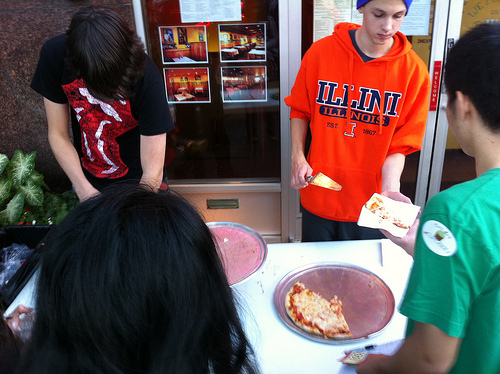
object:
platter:
[271, 261, 397, 344]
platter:
[202, 218, 270, 290]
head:
[39, 183, 253, 372]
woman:
[17, 175, 260, 374]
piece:
[349, 185, 432, 237]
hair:
[59, 4, 159, 112]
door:
[288, 0, 450, 245]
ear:
[451, 89, 472, 122]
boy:
[352, 19, 499, 373]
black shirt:
[30, 32, 176, 189]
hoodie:
[282, 21, 431, 223]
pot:
[270, 261, 396, 348]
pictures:
[149, 19, 270, 111]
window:
[138, 2, 285, 175]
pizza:
[362, 190, 413, 232]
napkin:
[356, 192, 421, 239]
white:
[272, 340, 299, 371]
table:
[279, 238, 387, 265]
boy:
[285, 1, 429, 241]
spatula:
[300, 171, 342, 191]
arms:
[137, 98, 167, 191]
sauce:
[284, 276, 352, 340]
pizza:
[285, 279, 351, 336]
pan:
[274, 260, 396, 344]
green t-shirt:
[396, 165, 499, 374]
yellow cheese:
[294, 289, 346, 330]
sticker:
[421, 220, 459, 258]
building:
[3, 4, 498, 370]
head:
[362, 0, 405, 46]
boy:
[31, 8, 170, 202]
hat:
[352, 0, 414, 10]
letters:
[315, 80, 403, 118]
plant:
[0, 142, 52, 222]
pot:
[4, 199, 70, 253]